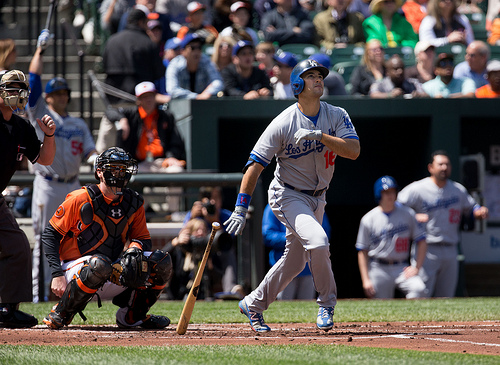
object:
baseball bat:
[176, 221, 221, 335]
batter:
[222, 60, 360, 333]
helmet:
[289, 58, 330, 98]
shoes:
[238, 298, 271, 332]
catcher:
[41, 145, 170, 329]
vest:
[47, 186, 150, 261]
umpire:
[0, 69, 55, 332]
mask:
[0, 69, 31, 115]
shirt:
[48, 184, 152, 261]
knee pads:
[79, 255, 113, 290]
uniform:
[243, 101, 358, 314]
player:
[354, 174, 426, 299]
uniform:
[355, 205, 428, 300]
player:
[397, 150, 488, 297]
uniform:
[397, 176, 480, 298]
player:
[24, 29, 100, 303]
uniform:
[24, 73, 94, 303]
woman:
[361, 0, 419, 67]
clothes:
[361, 13, 420, 49]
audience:
[164, 33, 225, 100]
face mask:
[99, 147, 138, 195]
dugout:
[191, 99, 497, 298]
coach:
[104, 81, 185, 211]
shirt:
[135, 106, 165, 161]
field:
[0, 297, 497, 365]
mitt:
[119, 247, 153, 290]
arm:
[23, 55, 45, 114]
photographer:
[161, 216, 234, 300]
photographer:
[181, 187, 244, 300]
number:
[324, 149, 329, 169]